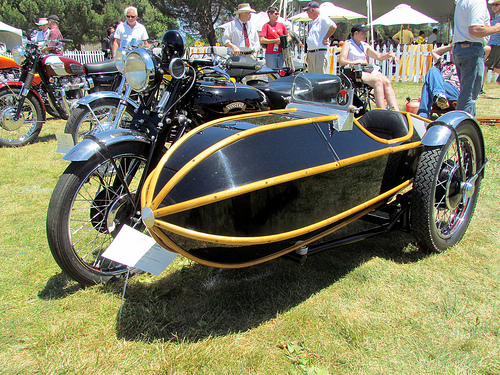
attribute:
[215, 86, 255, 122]
gas tank — red, white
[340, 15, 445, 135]
person — sitting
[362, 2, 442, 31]
umbrella — white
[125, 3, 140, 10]
hairline — receding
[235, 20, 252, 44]
tie — red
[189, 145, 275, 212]
lines — yellow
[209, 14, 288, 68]
tie — red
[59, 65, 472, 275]
motorcycle — zeppelin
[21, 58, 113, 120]
motorcycle — red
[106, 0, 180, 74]
man — gray haired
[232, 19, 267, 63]
tie — red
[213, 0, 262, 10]
hat — cowboy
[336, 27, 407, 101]
woman — sitting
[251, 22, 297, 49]
shirt — red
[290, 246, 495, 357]
grass — sectioned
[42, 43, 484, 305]
motorcycle — sidecar, front headlight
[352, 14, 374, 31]
hat — persons head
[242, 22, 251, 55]
tie — persons neck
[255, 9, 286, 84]
person — standing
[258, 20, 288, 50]
shirt — red 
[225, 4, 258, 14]
hat — wide brim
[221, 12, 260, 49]
shirt — white collared 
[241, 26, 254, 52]
tie —  red neck 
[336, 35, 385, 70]
shirt —   white 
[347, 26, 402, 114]
woman — chair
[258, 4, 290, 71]
man — red shirt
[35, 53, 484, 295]
vehicle — casting , shadow, black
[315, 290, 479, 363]
grass — green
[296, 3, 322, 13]
cap — ball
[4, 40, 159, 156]
motorcycle — parked together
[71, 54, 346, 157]
motorcycle — parked together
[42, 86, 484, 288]
motorcycle — parked together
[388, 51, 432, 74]
table — nearby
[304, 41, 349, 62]
table — nearby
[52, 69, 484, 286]
motorcycle — on display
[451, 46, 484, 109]
jeans — blue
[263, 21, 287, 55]
t-shirt — red